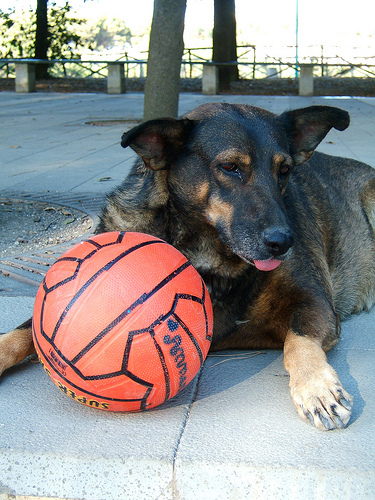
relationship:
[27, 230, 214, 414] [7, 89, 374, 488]
ball on ground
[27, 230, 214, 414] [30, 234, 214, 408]
ball with lines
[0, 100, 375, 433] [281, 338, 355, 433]
brindle dog has paw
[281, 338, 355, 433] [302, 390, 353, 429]
paw has nails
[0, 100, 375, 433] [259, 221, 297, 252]
brindle dog has nose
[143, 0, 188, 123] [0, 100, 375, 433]
tree behind brindle dog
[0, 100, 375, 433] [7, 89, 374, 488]
brindle dog laying on ground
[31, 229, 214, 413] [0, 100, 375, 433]
ball near brindle dog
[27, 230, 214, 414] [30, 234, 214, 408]
ball has lines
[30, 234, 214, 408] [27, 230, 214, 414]
lines on ball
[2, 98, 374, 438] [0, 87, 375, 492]
brindle dog laying on sidewalk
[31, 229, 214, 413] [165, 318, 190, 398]
ball with writing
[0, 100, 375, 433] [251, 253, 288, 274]
brindle dog with tongue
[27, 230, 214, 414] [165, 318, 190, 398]
ball with writing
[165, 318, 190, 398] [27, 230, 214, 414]
writing on ball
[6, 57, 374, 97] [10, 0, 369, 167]
benches in background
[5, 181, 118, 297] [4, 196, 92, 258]
drain cover with dirt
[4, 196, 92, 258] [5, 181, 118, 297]
dirt on drain cover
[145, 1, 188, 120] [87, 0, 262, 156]
tree trunk in middle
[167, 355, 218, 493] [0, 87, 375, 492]
crack in sidewalk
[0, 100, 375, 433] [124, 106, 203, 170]
brindle dog has ear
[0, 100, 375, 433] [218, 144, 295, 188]
brindle dog has eyes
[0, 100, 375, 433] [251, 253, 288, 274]
brindle dog has tongue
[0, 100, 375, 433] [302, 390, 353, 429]
brindle dog has nails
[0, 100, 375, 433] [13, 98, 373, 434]
brindle dog lying down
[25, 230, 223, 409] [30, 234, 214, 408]
football with lines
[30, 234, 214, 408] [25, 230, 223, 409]
lines on football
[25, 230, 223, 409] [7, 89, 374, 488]
football on ground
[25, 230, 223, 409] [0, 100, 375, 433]
football in front of brindle dog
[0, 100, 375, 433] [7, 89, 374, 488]
brindle dog lying on ground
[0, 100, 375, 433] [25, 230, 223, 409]
brindle dog lying next to football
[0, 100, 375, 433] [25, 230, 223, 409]
brindle dog next to football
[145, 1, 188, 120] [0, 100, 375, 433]
tree trunk behind brindle dog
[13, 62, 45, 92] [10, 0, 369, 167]
pillar in background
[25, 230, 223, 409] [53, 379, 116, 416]
football with letters